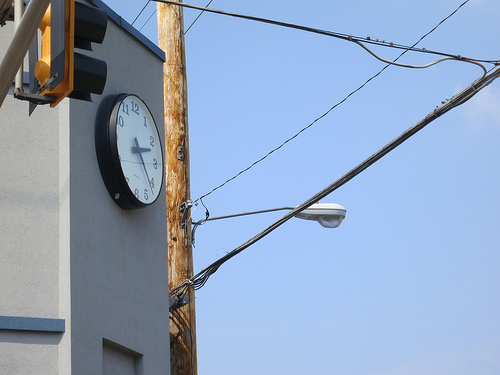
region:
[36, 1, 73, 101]
The yellow backing of the traffic light.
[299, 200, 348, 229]
The light of the light post.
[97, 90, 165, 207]
The clock on the building.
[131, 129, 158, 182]
The hands of the clock on the building.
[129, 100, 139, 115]
The number 12 on the clock.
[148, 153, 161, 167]
The number 3 on the clock.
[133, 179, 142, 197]
The number 6 on the clock.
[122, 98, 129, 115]
The number 11 on the clock.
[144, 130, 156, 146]
The number 2 on the clock.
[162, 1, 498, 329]
The wires in the air attached to the wooden pole.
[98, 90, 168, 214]
clock with white face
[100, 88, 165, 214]
clock with black numbers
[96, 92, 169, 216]
clock with black borders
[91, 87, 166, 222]
clock time says 2:22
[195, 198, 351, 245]
street lamp connected to wooden pole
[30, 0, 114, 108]
partial view of traffic lights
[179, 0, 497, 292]
electric wires connected to wooden pole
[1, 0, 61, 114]
metal post supports traffic light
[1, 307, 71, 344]
gray horizontal bar on cream-colored building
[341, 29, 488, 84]
curvature in bottom wire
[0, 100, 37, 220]
clock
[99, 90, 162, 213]
black and white clock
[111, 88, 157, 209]
black and white clock on building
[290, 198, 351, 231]
white street light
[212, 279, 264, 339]
white clouds against blue sky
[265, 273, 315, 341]
white clouds against blue sky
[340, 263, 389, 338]
white clouds against blue sky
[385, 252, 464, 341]
white clouds against blue sky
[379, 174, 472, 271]
white clouds against blue sky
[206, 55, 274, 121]
white clouds against blue sky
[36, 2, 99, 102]
black and yellow street light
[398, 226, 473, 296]
blue sky with no clouds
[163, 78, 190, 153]
wooden electrical pole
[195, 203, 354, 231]
metal street light on pole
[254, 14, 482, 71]
electrical wires over building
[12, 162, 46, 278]
gray side of building in the sunlight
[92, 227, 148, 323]
gray side of building in the shade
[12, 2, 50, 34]
gray metal pole holding stop light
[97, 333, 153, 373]
indention into the side of building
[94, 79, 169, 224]
A clock on the side of a building.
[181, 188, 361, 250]
a street light attached to a pole.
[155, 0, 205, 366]
a tall wooden power pole.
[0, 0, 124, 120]
a yellow traffic signal.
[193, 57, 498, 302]
power lines on a pole.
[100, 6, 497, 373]
a light blue clear sky.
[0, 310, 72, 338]
a decoration on a wall.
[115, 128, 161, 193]
clock hands on a clock.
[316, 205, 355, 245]
A light on a street light.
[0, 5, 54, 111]
a support pole on a traffic signal.